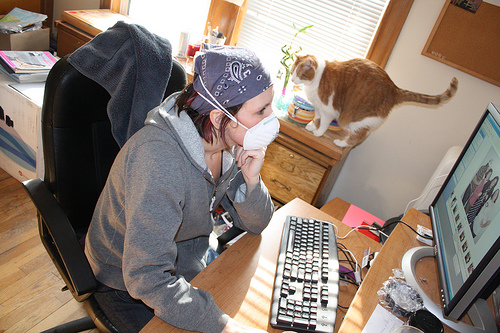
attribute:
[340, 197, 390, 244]
paper — pink 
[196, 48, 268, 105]
bandana — grey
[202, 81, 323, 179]
mask — white, face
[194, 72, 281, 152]
mask — white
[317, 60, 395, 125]
body — brown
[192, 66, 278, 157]
white mask — white 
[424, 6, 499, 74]
board — brown 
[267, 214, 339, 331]
computer keyborad — grey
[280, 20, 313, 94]
plant — small, green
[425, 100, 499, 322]
monitor — computer, display, silver , black , flatscreen 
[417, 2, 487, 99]
board — empty, bulletin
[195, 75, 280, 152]
face mask — white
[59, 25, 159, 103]
towel — dark blue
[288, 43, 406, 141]
cat — orange , white 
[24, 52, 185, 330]
chair — black, computer chair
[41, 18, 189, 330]
desk chair — black 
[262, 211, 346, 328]
computer keyboard — wired 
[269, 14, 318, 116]
plant — green, lucky, bamboo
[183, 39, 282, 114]
handkerchief — gray